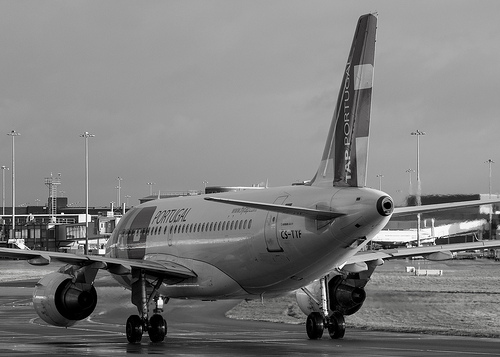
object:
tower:
[43, 170, 62, 214]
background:
[0, 1, 499, 258]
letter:
[183, 207, 191, 222]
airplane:
[0, 13, 500, 344]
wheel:
[126, 316, 142, 344]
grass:
[226, 254, 500, 338]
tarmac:
[1, 270, 498, 356]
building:
[0, 197, 130, 248]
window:
[29, 227, 41, 239]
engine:
[32, 270, 98, 327]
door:
[265, 195, 288, 252]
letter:
[152, 210, 161, 225]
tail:
[304, 13, 379, 188]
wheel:
[329, 313, 345, 340]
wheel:
[148, 314, 167, 342]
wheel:
[307, 312, 325, 337]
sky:
[0, 0, 499, 206]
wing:
[1, 245, 198, 282]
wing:
[345, 240, 499, 263]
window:
[162, 224, 168, 234]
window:
[247, 219, 251, 229]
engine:
[295, 273, 366, 317]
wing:
[204, 196, 347, 223]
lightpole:
[7, 129, 22, 231]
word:
[150, 207, 191, 223]